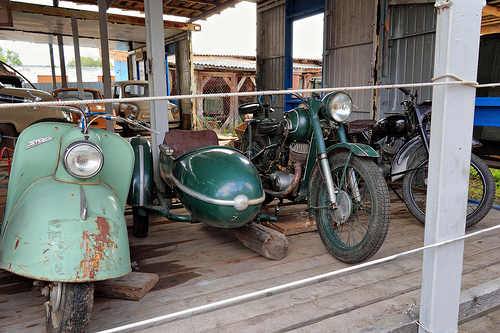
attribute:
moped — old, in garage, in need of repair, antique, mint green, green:
[3, 109, 164, 332]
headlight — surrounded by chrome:
[64, 140, 107, 181]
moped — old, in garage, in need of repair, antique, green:
[229, 89, 393, 266]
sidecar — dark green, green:
[131, 126, 273, 237]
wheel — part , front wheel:
[41, 279, 99, 332]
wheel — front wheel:
[306, 151, 392, 266]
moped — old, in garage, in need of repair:
[348, 91, 499, 230]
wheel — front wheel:
[403, 145, 495, 226]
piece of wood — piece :
[96, 273, 159, 302]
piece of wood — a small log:
[224, 223, 293, 265]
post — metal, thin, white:
[415, 1, 488, 331]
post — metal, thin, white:
[143, 2, 171, 201]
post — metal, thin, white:
[98, 0, 117, 130]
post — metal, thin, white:
[70, 16, 90, 111]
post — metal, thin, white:
[56, 32, 69, 90]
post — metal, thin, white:
[48, 43, 58, 93]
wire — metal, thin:
[0, 75, 498, 110]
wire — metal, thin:
[93, 222, 499, 332]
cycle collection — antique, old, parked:
[0, 88, 494, 331]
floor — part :
[1, 180, 497, 332]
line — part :
[276, 283, 423, 332]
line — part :
[137, 237, 238, 271]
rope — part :
[414, 320, 433, 333]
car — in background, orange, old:
[53, 87, 118, 131]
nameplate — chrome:
[27, 135, 55, 153]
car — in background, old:
[113, 80, 181, 132]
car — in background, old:
[0, 83, 71, 148]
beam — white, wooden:
[340, 49, 347, 89]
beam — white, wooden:
[351, 46, 359, 89]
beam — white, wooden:
[336, 3, 343, 46]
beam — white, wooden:
[360, 4, 367, 40]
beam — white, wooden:
[323, 52, 332, 87]